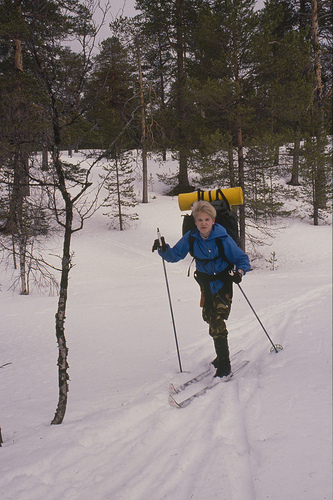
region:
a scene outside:
[9, 8, 331, 484]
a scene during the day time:
[8, 7, 320, 490]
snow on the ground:
[4, 130, 328, 497]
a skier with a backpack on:
[138, 167, 292, 417]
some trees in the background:
[2, 0, 330, 235]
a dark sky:
[52, 0, 159, 74]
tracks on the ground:
[71, 393, 264, 498]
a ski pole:
[143, 210, 191, 380]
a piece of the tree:
[240, 101, 259, 110]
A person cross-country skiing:
[143, 188, 286, 413]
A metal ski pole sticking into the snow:
[156, 255, 192, 377]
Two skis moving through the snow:
[164, 350, 251, 408]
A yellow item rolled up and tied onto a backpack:
[172, 189, 253, 210]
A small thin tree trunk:
[27, 173, 79, 454]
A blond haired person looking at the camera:
[188, 199, 217, 237]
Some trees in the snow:
[257, 164, 326, 226]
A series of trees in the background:
[123, 80, 295, 146]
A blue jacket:
[155, 230, 261, 289]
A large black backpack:
[181, 197, 248, 267]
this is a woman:
[130, 179, 269, 401]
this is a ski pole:
[221, 267, 279, 363]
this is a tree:
[30, 103, 79, 430]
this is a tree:
[142, 17, 205, 196]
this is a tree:
[294, 18, 330, 237]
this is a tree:
[111, 24, 158, 209]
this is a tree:
[140, 23, 179, 155]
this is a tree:
[0, 19, 31, 255]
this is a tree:
[216, 18, 289, 188]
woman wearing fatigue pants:
[190, 283, 237, 339]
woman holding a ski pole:
[151, 224, 190, 381]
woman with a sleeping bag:
[170, 181, 247, 210]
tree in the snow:
[40, 283, 73, 438]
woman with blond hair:
[187, 200, 219, 237]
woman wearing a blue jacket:
[170, 222, 242, 290]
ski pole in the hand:
[153, 224, 185, 373]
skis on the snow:
[162, 346, 251, 409]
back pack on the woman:
[172, 183, 242, 263]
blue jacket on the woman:
[140, 196, 253, 296]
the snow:
[267, 392, 312, 445]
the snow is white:
[160, 447, 212, 486]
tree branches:
[27, 251, 49, 275]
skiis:
[237, 286, 266, 317]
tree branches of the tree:
[259, 187, 287, 221]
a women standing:
[173, 207, 244, 392]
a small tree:
[98, 154, 137, 224]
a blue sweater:
[224, 242, 241, 263]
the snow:
[188, 414, 221, 454]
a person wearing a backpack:
[153, 187, 280, 406]